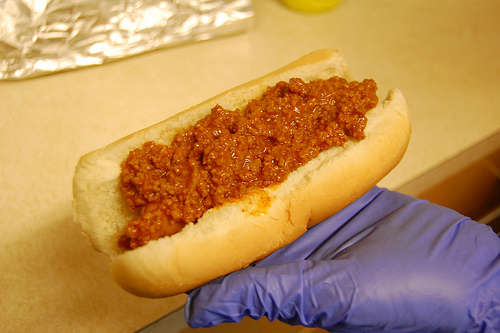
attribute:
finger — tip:
[184, 267, 359, 319]